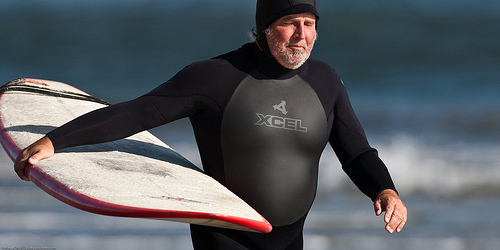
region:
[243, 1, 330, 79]
the man has his eyes closed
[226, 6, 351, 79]
the man has a beard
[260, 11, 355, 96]
his beard is grey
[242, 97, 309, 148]
his wet suit says xcel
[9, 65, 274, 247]
the surfboard is white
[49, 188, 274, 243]
the board has red trim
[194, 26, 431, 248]
the man's wet suit is grey & black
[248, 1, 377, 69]
the man is wearing a cap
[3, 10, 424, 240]
the man is carrying his surfboard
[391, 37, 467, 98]
the sea is in the background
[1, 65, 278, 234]
The white surfboard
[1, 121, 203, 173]
The shadow on the board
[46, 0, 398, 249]
The black wetsuit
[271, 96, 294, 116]
The logo on the wetsuit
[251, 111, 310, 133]
The name of the wetsuit maker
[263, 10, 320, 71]
The face of the man holding the board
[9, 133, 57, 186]
The right hand of the man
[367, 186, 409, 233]
The left hand of the man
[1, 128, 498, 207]
The wave behind the man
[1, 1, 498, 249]
The ocean behind the man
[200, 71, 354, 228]
A man in black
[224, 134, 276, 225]
A man in black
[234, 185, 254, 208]
A man in black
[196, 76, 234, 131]
A man in black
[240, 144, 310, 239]
A man in black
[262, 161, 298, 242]
A man in black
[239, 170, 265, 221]
A man in black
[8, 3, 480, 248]
man carrying a surfboard on a beach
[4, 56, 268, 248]
red and white surfboard in a man's hand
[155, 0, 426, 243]
man wearing a black body suit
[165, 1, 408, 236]
man wearing a black surf suit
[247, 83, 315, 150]
Xcel logo on a black body suit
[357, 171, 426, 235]
hand of a man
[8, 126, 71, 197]
hand of a man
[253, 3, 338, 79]
man with white facial hair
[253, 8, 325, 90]
man with a white beard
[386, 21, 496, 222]
ocean waves behind a man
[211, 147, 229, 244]
the surf board is red and white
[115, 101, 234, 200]
the surf board is red and white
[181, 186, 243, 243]
the surf board is red and white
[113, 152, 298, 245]
the surf board is red and white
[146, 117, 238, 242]
the surf board is red and white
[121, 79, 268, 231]
the surf board is red and white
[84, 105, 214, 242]
the surf board is red and white